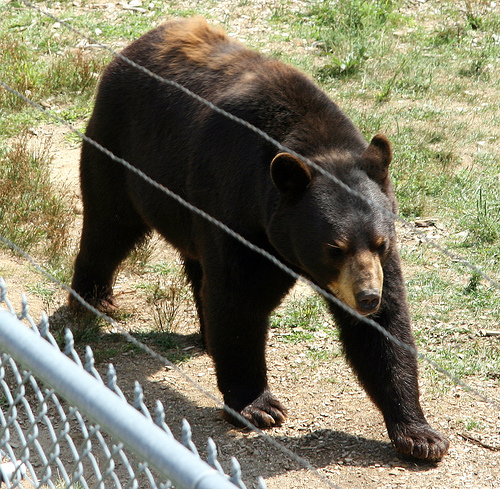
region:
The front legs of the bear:
[193, 267, 450, 458]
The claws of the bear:
[244, 400, 287, 426]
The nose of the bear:
[358, 288, 378, 305]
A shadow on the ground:
[1, 330, 411, 487]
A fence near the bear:
[0, 285, 274, 487]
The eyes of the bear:
[328, 240, 388, 257]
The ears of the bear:
[270, 132, 390, 190]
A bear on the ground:
[71, 19, 447, 458]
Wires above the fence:
[2, 1, 498, 487]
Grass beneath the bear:
[1, 0, 498, 303]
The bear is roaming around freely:
[40, 16, 470, 476]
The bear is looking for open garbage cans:
[55, 17, 471, 477]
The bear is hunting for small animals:
[53, 6, 496, 476]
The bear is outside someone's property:
[22, 25, 484, 485]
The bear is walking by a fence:
[56, 5, 482, 481]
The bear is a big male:
[55, 10, 481, 475]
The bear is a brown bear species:
[50, 7, 476, 472]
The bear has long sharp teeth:
[50, 10, 475, 466]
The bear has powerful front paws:
[35, 6, 475, 477]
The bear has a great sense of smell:
[53, 14, 468, 464]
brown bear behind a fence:
[65, 28, 454, 463]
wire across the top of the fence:
[51, 6, 390, 251]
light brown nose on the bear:
[323, 250, 402, 313]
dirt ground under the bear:
[285, 409, 362, 482]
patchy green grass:
[411, 82, 481, 216]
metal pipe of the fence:
[20, 322, 125, 431]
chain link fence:
[9, 302, 137, 460]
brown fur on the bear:
[114, 86, 168, 139]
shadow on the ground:
[39, 375, 281, 486]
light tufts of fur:
[176, 17, 211, 57]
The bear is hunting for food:
[10, 13, 470, 469]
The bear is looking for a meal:
[36, 15, 462, 475]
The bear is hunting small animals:
[37, 10, 467, 478]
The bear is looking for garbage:
[40, 3, 480, 478]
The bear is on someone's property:
[37, 12, 482, 475]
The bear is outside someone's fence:
[60, 7, 475, 470]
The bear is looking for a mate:
[31, 7, 466, 485]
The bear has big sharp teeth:
[35, 7, 496, 485]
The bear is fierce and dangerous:
[55, 10, 466, 476]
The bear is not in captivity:
[34, 10, 467, 475]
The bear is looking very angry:
[46, 10, 473, 466]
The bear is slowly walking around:
[52, 12, 457, 468]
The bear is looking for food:
[50, 21, 476, 482]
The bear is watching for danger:
[50, 10, 476, 445]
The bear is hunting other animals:
[53, 2, 493, 482]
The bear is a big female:
[62, 25, 475, 466]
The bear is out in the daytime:
[46, 6, 474, 481]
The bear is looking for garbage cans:
[63, 5, 474, 471]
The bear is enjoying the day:
[48, 8, 475, 478]